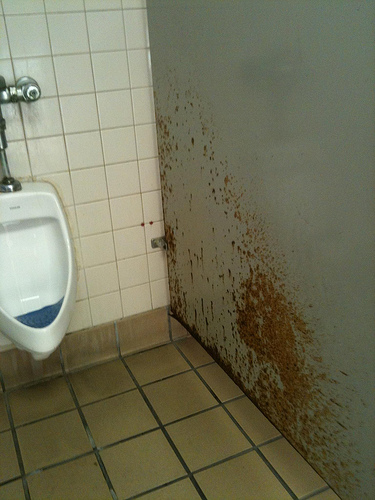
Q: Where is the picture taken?
A: A bathroom.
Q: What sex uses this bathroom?
A: Male.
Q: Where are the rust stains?
A: On the metal wall.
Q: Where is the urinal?
A: On the tile wall.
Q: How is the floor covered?
A: With tiles.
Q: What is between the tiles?
A: Grout.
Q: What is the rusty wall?
A: A divider.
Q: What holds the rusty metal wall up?
A: Brackets and bolts.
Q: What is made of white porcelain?
A: The urinal.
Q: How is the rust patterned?
A: As a splash.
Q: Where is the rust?
A: On the stall wall.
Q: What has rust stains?
A: Stall wall in bathroom.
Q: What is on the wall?
A: White urinal.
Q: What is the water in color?
A: Blue.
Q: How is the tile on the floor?
A: It is fading.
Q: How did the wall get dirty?
A: Someone missed.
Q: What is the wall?
A: Off white.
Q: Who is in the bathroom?
A: No one.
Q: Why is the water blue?
A: To clean it.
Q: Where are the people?
A: Taking the photo.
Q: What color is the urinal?
A: White.